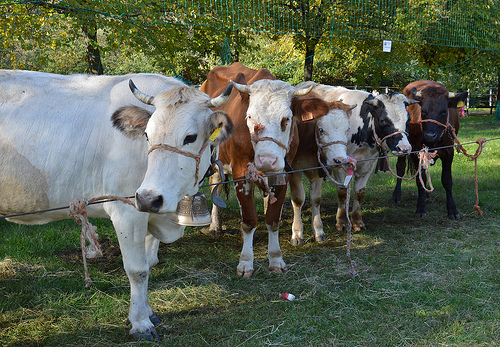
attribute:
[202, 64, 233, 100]
fur — brown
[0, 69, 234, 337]
cow — white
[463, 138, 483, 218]
rope — brown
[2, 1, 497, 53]
fince — green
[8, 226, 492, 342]
grass — green, brown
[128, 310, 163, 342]
hove — tan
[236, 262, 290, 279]
hove — tan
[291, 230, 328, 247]
hove — tan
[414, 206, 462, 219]
hove — tan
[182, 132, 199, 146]
eye — round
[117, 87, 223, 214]
head — white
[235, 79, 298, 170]
head — white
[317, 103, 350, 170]
head — white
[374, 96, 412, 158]
head — white, black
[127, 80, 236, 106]
horns — white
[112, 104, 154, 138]
ear — grey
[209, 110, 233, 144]
ear — grey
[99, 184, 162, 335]
leg — white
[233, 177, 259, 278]
leg — brown, white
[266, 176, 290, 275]
leg — brown, white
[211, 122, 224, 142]
tag — yellow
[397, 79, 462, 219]
cow — brown, at back